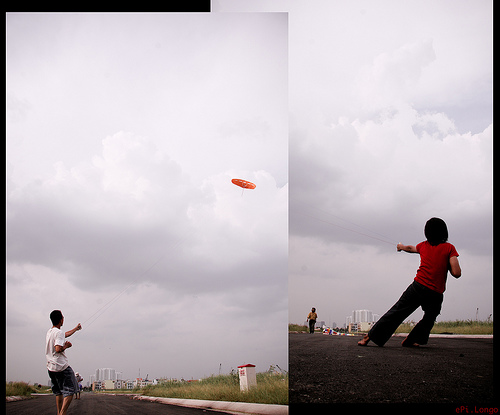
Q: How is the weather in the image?
A: It is cloudy.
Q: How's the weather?
A: It is cloudy.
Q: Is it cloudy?
A: Yes, it is cloudy.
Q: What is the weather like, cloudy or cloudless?
A: It is cloudy.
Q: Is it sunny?
A: No, it is cloudy.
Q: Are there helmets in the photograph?
A: No, there are no helmets.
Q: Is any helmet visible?
A: No, there are no helmets.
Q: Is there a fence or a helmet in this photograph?
A: No, there are no helmets or fences.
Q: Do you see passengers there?
A: No, there are no passengers.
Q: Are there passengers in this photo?
A: No, there are no passengers.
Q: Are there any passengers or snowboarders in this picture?
A: No, there are no passengers or snowboarders.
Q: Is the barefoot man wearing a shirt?
A: Yes, the man is wearing a shirt.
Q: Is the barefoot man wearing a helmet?
A: No, the man is wearing a shirt.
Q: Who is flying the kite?
A: The man is flying the kite.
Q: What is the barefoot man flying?
A: The man is flying the kite.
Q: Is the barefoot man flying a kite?
A: Yes, the man is flying a kite.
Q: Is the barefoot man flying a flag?
A: No, the man is flying a kite.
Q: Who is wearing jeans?
A: The man is wearing jeans.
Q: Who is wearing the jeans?
A: The man is wearing jeans.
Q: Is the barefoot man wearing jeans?
A: Yes, the man is wearing jeans.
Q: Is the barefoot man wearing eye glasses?
A: No, the man is wearing jeans.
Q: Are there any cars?
A: No, there are no cars.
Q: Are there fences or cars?
A: No, there are no cars or fences.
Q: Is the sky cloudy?
A: Yes, the sky is cloudy.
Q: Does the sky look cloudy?
A: Yes, the sky is cloudy.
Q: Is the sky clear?
A: No, the sky is cloudy.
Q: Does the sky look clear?
A: No, the sky is cloudy.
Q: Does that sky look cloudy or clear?
A: The sky is cloudy.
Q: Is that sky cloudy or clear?
A: The sky is cloudy.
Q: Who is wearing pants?
A: The man is wearing pants.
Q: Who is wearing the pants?
A: The man is wearing pants.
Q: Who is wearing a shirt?
A: The man is wearing a shirt.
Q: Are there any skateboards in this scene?
A: No, there are no skateboards.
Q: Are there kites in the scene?
A: Yes, there is a kite.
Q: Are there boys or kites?
A: Yes, there is a kite.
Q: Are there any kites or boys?
A: Yes, there is a kite.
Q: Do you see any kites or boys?
A: Yes, there is a kite.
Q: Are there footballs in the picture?
A: No, there are no footballs.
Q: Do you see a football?
A: No, there are no footballs.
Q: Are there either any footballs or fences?
A: No, there are no footballs or fences.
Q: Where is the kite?
A: The kite is in the sky.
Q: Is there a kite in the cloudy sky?
A: Yes, there is a kite in the sky.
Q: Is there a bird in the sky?
A: No, there is a kite in the sky.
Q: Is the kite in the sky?
A: Yes, the kite is in the sky.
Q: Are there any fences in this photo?
A: No, there are no fences.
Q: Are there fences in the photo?
A: No, there are no fences.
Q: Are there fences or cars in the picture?
A: No, there are no fences or cars.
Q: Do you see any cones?
A: No, there are no cones.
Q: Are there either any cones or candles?
A: No, there are no cones or candles.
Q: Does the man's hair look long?
A: Yes, the hair is long.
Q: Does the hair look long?
A: Yes, the hair is long.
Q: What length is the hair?
A: The hair is long.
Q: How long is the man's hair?
A: The hair is long.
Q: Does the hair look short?
A: No, the hair is long.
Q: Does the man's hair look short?
A: No, the hair is long.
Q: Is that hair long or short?
A: The hair is long.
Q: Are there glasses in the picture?
A: No, there are no glasses.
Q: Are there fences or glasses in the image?
A: No, there are no glasses or fences.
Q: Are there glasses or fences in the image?
A: No, there are no glasses or fences.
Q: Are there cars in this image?
A: No, there are no cars.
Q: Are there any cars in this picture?
A: No, there are no cars.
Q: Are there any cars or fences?
A: No, there are no cars or fences.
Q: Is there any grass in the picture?
A: Yes, there is grass.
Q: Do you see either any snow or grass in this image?
A: Yes, there is grass.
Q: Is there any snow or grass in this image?
A: Yes, there is grass.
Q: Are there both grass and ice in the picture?
A: No, there is grass but no ice.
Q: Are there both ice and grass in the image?
A: No, there is grass but no ice.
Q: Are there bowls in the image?
A: No, there are no bowls.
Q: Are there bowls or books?
A: No, there are no bowls or books.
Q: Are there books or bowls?
A: No, there are no bowls or books.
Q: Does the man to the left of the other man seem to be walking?
A: Yes, the man is walking.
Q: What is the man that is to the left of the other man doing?
A: The man is walking.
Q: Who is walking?
A: The man is walking.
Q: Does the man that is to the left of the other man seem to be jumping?
A: No, the man is walking.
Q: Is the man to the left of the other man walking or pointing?
A: The man is walking.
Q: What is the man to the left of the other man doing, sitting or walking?
A: The man is walking.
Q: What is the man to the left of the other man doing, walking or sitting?
A: The man is walking.